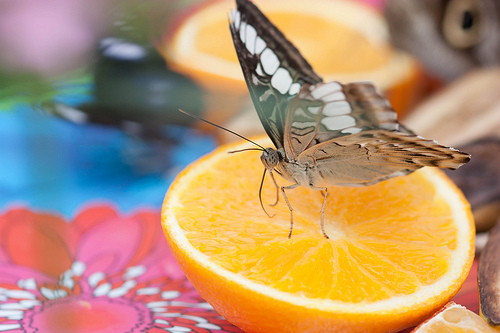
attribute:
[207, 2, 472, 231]
butterfly — gray, spotty, large, standing, black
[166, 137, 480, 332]
orange — halved, white, sliced, distant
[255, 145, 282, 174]
head — small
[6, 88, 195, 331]
table cloth — flowered, patterned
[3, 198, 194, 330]
flower — pink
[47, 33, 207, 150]
butterfly — purple, black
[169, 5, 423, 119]
orange — out of focus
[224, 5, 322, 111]
wing — black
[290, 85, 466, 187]
wing — black